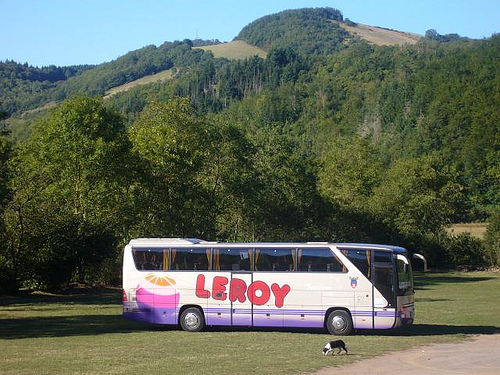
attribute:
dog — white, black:
[321, 339, 353, 357]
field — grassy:
[2, 284, 496, 372]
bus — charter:
[107, 224, 413, 325]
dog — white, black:
[322, 340, 348, 356]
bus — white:
[119, 238, 431, 333]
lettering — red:
[191, 276, 291, 313]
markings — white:
[317, 345, 336, 351]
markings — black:
[327, 341, 354, 351]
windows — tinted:
[129, 244, 327, 270]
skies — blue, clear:
[44, 18, 154, 46]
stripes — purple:
[127, 302, 384, 330]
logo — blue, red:
[186, 274, 311, 308]